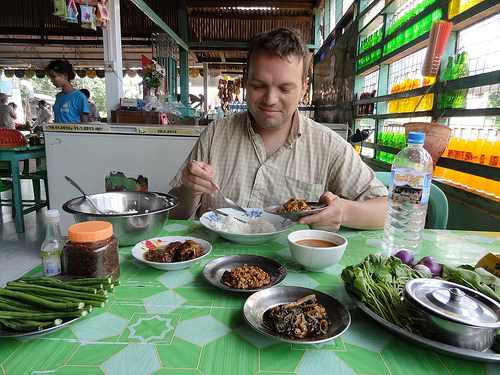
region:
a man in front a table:
[162, 21, 396, 284]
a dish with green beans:
[1, 261, 123, 348]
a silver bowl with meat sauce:
[234, 278, 357, 352]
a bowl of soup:
[287, 223, 349, 275]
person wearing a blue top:
[35, 49, 97, 141]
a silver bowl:
[59, 168, 186, 246]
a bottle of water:
[380, 123, 435, 260]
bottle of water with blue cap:
[381, 120, 441, 264]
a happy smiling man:
[196, 17, 355, 180]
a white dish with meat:
[127, 231, 217, 273]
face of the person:
[226, 40, 316, 142]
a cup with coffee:
[286, 204, 362, 277]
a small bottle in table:
[59, 206, 141, 286]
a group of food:
[135, 208, 360, 358]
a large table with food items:
[10, 170, 497, 348]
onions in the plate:
[383, 242, 452, 280]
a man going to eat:
[181, 23, 403, 259]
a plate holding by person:
[271, 191, 321, 215]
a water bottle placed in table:
[378, 125, 465, 298]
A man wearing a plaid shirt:
[171, 25, 383, 195]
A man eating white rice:
[163, 22, 376, 237]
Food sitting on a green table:
[125, 235, 354, 370]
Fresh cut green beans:
[2, 268, 124, 370]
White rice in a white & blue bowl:
[196, 203, 296, 243]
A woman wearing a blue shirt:
[37, 58, 97, 125]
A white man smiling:
[216, 28, 323, 135]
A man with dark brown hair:
[219, 20, 321, 147]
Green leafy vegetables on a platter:
[334, 249, 499, 350]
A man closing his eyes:
[235, 24, 317, 135]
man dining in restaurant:
[167, 24, 392, 232]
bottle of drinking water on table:
[383, 130, 435, 253]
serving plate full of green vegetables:
[0, 270, 122, 342]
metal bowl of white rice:
[59, 187, 181, 247]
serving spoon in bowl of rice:
[61, 173, 108, 214]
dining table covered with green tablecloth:
[0, 212, 499, 374]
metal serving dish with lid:
[406, 277, 498, 352]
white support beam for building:
[103, 66, 125, 123]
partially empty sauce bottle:
[39, 208, 64, 280]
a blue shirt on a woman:
[51, 85, 93, 124]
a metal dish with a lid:
[406, 274, 498, 345]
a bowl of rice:
[195, 205, 295, 241]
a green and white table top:
[0, 216, 498, 374]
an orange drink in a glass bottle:
[465, 122, 477, 189]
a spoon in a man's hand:
[190, 155, 250, 214]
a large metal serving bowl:
[60, 180, 173, 250]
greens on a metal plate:
[342, 253, 417, 331]